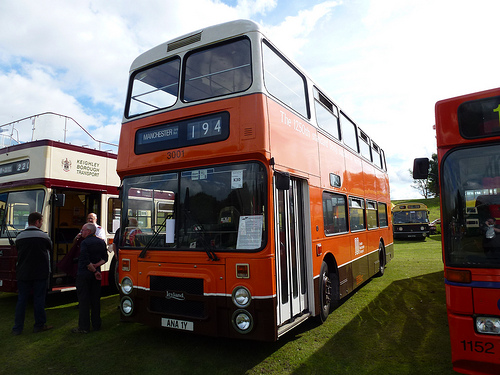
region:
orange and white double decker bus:
[117, 14, 402, 342]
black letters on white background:
[157, 310, 198, 336]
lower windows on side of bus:
[320, 186, 390, 238]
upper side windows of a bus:
[258, 33, 391, 173]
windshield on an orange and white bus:
[116, 152, 275, 263]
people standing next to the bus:
[4, 202, 114, 362]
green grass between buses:
[396, 241, 446, 361]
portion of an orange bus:
[434, 95, 491, 365]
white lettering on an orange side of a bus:
[348, 236, 370, 257]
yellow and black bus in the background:
[379, 197, 436, 244]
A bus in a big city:
[45, 11, 486, 368]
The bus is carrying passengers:
[57, 15, 462, 360]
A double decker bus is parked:
[65, 8, 447, 358]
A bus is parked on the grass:
[52, 20, 495, 371]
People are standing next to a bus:
[10, 21, 432, 371]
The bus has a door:
[267, 166, 314, 331]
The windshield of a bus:
[171, 163, 261, 254]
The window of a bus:
[178, 42, 251, 93]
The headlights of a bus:
[226, 285, 251, 331]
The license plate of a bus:
[155, 315, 197, 332]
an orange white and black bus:
[113, 33, 395, 339]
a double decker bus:
[118, 16, 396, 348]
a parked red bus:
[416, 82, 499, 374]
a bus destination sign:
[135, 123, 182, 148]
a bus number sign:
[184, 113, 224, 142]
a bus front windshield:
[118, 175, 267, 252]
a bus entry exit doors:
[270, 171, 312, 323]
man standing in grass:
[69, 222, 106, 332]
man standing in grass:
[11, 210, 58, 336]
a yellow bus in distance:
[390, 196, 431, 244]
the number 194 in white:
[186, 118, 223, 138]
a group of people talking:
[16, 205, 112, 335]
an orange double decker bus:
[112, 18, 397, 350]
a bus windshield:
[124, 154, 271, 249]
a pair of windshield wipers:
[137, 203, 223, 265]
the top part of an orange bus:
[123, 46, 393, 193]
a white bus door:
[271, 176, 323, 326]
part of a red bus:
[413, 90, 498, 372]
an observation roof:
[0, 108, 124, 181]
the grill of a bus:
[117, 269, 259, 331]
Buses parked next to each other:
[11, 28, 498, 361]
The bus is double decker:
[121, 22, 396, 337]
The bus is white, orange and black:
[106, 23, 398, 330]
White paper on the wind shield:
[230, 205, 269, 256]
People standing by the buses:
[14, 197, 124, 329]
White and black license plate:
[154, 311, 199, 335]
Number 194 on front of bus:
[177, 115, 229, 141]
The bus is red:
[425, 87, 495, 367]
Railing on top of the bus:
[3, 111, 114, 160]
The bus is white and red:
[5, 115, 122, 305]